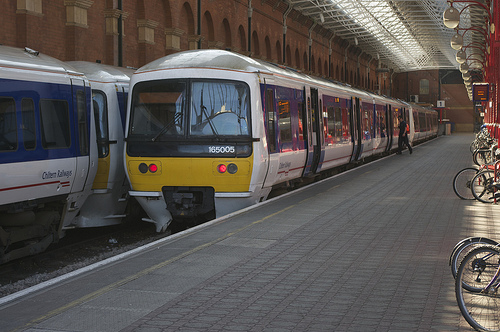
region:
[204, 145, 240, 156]
The numbers on the front of the train.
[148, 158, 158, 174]
The red light on the left side of the yellow train.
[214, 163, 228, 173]
The red light on the front of the train.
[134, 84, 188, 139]
The left window of the yellow and white train.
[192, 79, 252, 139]
The right window of the yellow and white train.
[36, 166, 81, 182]
The letters on the side of the train on the left.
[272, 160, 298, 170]
The letters on the side of the train on the right.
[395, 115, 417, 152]
The person walking into the train.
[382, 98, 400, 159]
The double doors the person is entering on the train.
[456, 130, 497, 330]
The bikes that are lined up to the right of the train.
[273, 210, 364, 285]
the ground is gray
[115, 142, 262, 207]
the paint is yellow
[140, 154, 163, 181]
the light is red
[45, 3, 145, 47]
the brick is brown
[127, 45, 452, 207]
the train is white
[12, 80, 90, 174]
the paint is blue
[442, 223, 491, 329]
the bike is standing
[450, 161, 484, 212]
the tire is round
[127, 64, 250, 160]
the window is shiny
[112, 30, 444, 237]
the train has stopped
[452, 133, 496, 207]
bikes parked on train platform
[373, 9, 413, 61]
skylights in station roof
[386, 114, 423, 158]
man getting on train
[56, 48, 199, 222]
two trains at station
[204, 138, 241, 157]
number on front of train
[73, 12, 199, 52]
brick wall across from platform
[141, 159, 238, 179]
red lights on train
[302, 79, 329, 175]
open door on side of train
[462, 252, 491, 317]
spokes on bike wheel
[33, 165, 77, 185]
words on side of train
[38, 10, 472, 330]
this is a terminal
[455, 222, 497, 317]
these are bicycle wheels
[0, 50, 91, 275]
this is a train car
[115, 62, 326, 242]
this is the front of a train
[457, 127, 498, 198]
these are a bunch of bicycles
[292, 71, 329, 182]
this is a door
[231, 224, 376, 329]
this is the color gray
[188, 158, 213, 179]
this is the color yellow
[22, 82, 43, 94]
this is the color blue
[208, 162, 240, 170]
this is a headlight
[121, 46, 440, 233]
long white train in front of other train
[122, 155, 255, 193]
yellow front of train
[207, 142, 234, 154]
white numbers on front of train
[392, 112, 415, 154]
person walking near train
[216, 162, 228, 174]
red light on front of train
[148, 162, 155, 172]
red light on front of train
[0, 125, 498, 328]
grey paved platform near train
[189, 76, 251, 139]
large window on front of train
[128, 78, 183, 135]
large window on front of train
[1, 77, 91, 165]
blue side of train